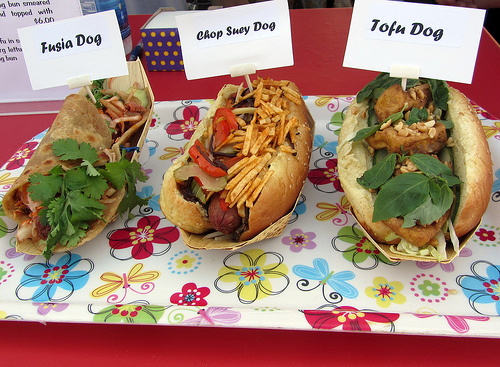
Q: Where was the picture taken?
A: At a restaurant.